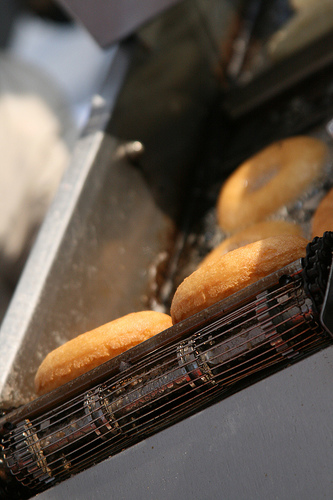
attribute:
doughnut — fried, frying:
[220, 187, 297, 268]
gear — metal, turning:
[192, 269, 291, 390]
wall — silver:
[239, 429, 283, 459]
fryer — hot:
[211, 70, 310, 249]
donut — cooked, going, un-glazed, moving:
[192, 221, 282, 297]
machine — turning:
[68, 43, 313, 404]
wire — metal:
[158, 338, 293, 411]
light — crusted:
[205, 145, 322, 195]